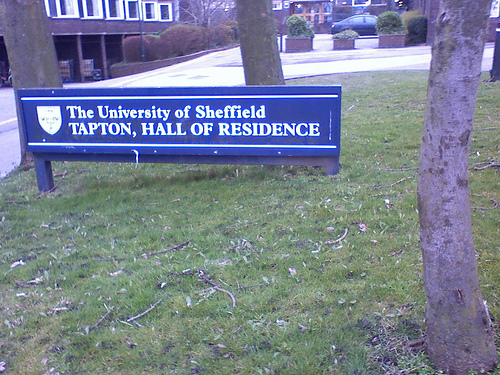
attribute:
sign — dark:
[8, 68, 358, 208]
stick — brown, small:
[187, 267, 246, 319]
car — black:
[327, 8, 381, 38]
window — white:
[44, 0, 55, 20]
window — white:
[59, 0, 64, 18]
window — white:
[81, 0, 96, 20]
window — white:
[159, 3, 172, 21]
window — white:
[122, 3, 140, 19]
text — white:
[62, 104, 322, 138]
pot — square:
[284, 28, 316, 55]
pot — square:
[330, 36, 360, 52]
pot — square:
[376, 30, 412, 49]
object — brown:
[53, 57, 77, 82]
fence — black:
[55, 62, 109, 79]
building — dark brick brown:
[1, 0, 183, 91]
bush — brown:
[118, 30, 154, 76]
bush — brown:
[153, 17, 217, 68]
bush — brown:
[205, 20, 237, 51]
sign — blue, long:
[12, 84, 343, 161]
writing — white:
[64, 101, 321, 135]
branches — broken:
[0, 183, 412, 362]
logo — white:
[34, 100, 64, 135]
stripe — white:
[23, 139, 339, 150]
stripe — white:
[17, 92, 333, 100]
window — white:
[156, 0, 176, 24]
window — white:
[134, 0, 158, 24]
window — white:
[102, 0, 118, 21]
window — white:
[39, 0, 61, 16]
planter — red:
[282, 30, 319, 53]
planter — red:
[331, 36, 358, 52]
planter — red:
[373, 33, 412, 46]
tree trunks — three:
[2, 24, 484, 354]